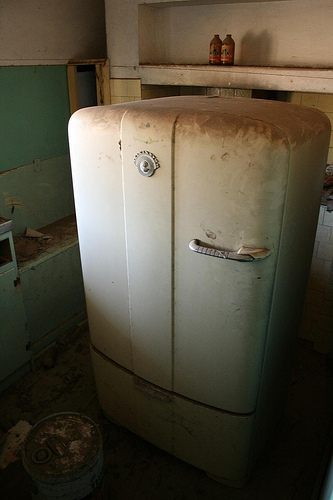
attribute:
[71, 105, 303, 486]
fridge — white, antique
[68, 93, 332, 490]
fridge — long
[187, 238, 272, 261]
handle — silver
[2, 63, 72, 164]
wall — exposed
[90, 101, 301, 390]
refrigerator — rusty, old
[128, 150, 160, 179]
logo — silver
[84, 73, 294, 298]
fridge — white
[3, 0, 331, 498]
kitchen — dingy, old, ripped up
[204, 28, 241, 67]
botttles — old, sitting on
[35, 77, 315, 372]
refirgerator — old, white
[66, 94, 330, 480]
chest — dirty, old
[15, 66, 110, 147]
wall — dirty, green